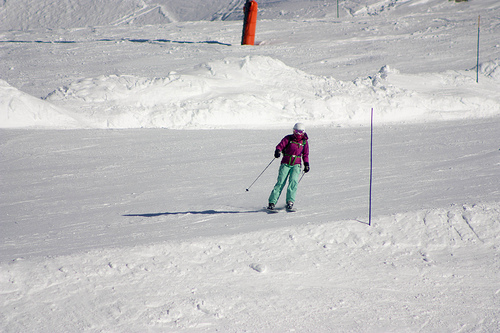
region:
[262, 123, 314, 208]
skier in white snow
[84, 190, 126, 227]
white snow on hill side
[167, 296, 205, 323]
white snow on hill side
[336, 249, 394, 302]
white snow on hill side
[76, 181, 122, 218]
white snow on hill side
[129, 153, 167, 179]
white snow on hill side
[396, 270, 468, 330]
snow is white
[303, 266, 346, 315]
the snow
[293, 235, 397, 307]
the white snow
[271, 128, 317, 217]
a person is skiing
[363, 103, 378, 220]
a long pole in the snow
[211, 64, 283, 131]
a small snow mountain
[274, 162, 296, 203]
green pants the person is wearing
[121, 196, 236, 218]
a shadow on the snow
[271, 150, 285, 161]
person is holding a ski pole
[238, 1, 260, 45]
a red pole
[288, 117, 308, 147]
the helmet is white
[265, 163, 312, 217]
the pants are green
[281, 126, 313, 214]
skier in snow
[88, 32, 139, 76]
white clouds in blue sky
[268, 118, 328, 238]
skier on snow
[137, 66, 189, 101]
white clouds in blue sky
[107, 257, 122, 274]
snow clump on the ski slope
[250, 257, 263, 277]
snow clump on the ski slope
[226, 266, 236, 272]
snow clump on the ski slope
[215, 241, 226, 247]
snow clump on the ski slope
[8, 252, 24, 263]
snow clump on the ski slope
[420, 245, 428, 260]
snow clump on the ski slope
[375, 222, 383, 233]
snow clump on the ski slope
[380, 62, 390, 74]
snow clump on the ski slope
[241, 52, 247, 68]
snow clump on the ski slope